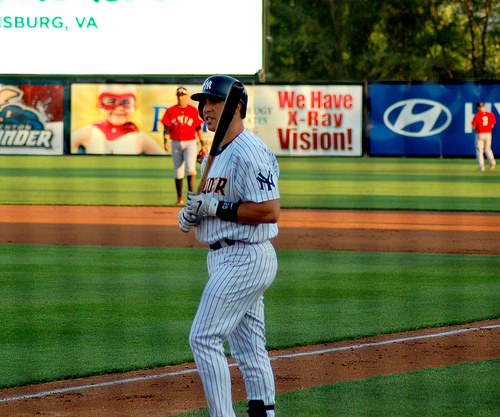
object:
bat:
[177, 82, 243, 234]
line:
[0, 319, 499, 404]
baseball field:
[0, 154, 498, 416]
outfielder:
[471, 98, 496, 173]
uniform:
[470, 110, 498, 167]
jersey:
[470, 109, 495, 136]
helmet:
[190, 73, 248, 122]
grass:
[1, 156, 499, 416]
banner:
[366, 81, 498, 161]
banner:
[66, 83, 366, 158]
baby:
[69, 83, 168, 155]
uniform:
[185, 126, 283, 415]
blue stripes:
[186, 128, 281, 416]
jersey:
[190, 126, 282, 249]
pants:
[183, 239, 277, 416]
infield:
[0, 237, 499, 415]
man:
[160, 86, 208, 204]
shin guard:
[173, 178, 183, 198]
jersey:
[159, 104, 204, 143]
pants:
[167, 138, 196, 180]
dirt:
[0, 203, 500, 257]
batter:
[173, 72, 283, 416]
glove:
[181, 188, 221, 221]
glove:
[174, 209, 202, 235]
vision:
[274, 129, 346, 152]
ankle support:
[243, 399, 275, 416]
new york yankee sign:
[255, 170, 275, 194]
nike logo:
[194, 200, 201, 214]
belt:
[205, 237, 235, 255]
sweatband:
[213, 200, 240, 224]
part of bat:
[209, 79, 243, 157]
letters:
[212, 176, 227, 198]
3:
[479, 114, 489, 128]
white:
[263, 133, 275, 147]